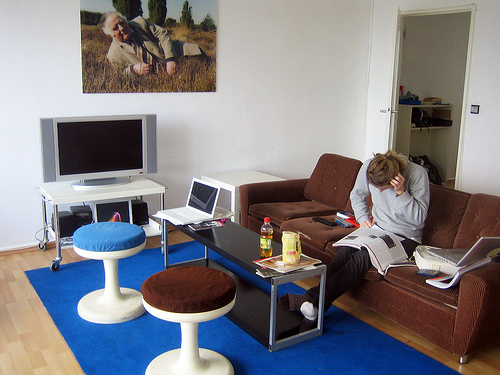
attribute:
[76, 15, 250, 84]
picture — large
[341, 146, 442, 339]
person — reading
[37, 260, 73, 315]
rug — blue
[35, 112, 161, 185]
television — off, flat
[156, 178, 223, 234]
laptop — white, powered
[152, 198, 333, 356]
table — black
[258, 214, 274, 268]
bottle — clear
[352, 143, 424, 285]
man — sitting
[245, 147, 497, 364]
couch — brown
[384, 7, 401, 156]
door — ajar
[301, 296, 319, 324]
sock — white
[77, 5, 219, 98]
picture — white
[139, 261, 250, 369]
stool — white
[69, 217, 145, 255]
stool cushion — blue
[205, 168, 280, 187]
end table — white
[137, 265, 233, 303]
cushion — brown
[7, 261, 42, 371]
floor — wood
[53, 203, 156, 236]
speakers — black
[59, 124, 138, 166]
screen — black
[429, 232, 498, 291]
laptop — gray